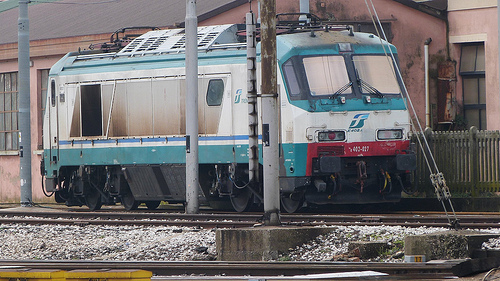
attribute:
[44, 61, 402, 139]
stripe — white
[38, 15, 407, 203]
train — blue, white, here, short, motionless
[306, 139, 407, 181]
stripe — red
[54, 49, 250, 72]
stripe — blue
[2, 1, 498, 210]
building — pink, small, red, dull pink, here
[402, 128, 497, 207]
fence — small, wooden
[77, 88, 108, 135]
window — open, here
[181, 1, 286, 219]
poles — large, metal, here, rusty, metallic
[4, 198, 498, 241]
train tracks — rough, rugged, metallic, here, long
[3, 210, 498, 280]
gravel — small, grey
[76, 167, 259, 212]
wheels — black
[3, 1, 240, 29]
roof — grey